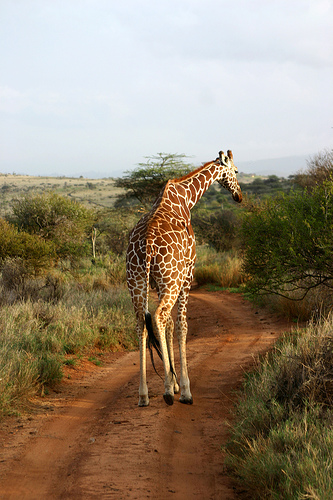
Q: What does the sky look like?
A: Cloudy.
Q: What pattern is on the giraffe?
A: Spots.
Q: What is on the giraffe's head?
A: Horns.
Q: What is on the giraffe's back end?
A: Tail.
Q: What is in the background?
A: Field.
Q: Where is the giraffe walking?
A: On a red clay road.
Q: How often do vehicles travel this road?
A: Fairly often.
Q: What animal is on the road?
A: A giraffe.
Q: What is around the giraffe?
A: Grass and trees.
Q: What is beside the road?
A: Medium-height grass.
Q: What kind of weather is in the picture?
A: Overcast.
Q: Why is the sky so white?
A: It's covered in clouds.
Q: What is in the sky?
A: A lot of clouds.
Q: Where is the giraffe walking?
A: Along a dirt road.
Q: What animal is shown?
A: Giraffe.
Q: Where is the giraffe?
A: On a path.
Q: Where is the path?
A: In the wild.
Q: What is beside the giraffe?
A: A bush.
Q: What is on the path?
A: A giraffe.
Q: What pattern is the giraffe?
A: Spotted.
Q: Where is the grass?
A: On the ground.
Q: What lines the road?
A: Grass.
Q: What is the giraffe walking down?
A: A dirt road.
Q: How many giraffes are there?
A: One.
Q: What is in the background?
A: Shrubs.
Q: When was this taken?
A: During the day.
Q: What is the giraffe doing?
A: Walking.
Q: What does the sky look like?
A: It is cloudy.